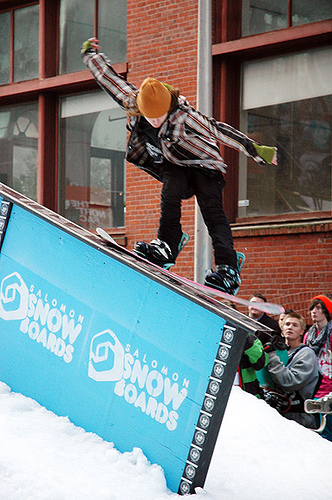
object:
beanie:
[136, 77, 171, 118]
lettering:
[117, 344, 192, 434]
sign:
[0, 203, 229, 499]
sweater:
[233, 332, 269, 400]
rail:
[0, 174, 279, 334]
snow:
[2, 381, 166, 496]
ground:
[3, 365, 332, 498]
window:
[228, 0, 331, 226]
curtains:
[240, 48, 332, 111]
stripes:
[240, 332, 270, 400]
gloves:
[80, 36, 95, 54]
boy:
[80, 34, 278, 294]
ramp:
[0, 180, 248, 499]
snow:
[210, 391, 331, 499]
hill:
[0, 347, 332, 500]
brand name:
[87, 330, 192, 434]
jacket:
[125, 118, 228, 181]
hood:
[169, 88, 188, 125]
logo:
[87, 328, 124, 387]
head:
[136, 77, 171, 128]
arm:
[82, 50, 132, 109]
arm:
[197, 118, 251, 155]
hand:
[80, 36, 101, 57]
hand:
[253, 142, 278, 165]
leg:
[157, 179, 184, 246]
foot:
[133, 237, 176, 270]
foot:
[203, 264, 241, 296]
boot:
[132, 235, 190, 270]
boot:
[204, 252, 247, 296]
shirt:
[142, 132, 165, 165]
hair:
[288, 311, 302, 318]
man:
[266, 307, 319, 420]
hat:
[309, 295, 331, 316]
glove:
[253, 143, 276, 166]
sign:
[65, 197, 108, 230]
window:
[0, 0, 127, 235]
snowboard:
[95, 224, 285, 326]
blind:
[238, 51, 331, 112]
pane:
[0, 0, 42, 80]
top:
[0, 2, 135, 102]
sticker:
[238, 200, 250, 208]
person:
[238, 293, 281, 400]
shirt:
[232, 333, 269, 399]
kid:
[302, 293, 332, 427]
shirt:
[303, 326, 329, 354]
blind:
[60, 87, 118, 120]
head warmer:
[306, 293, 332, 309]